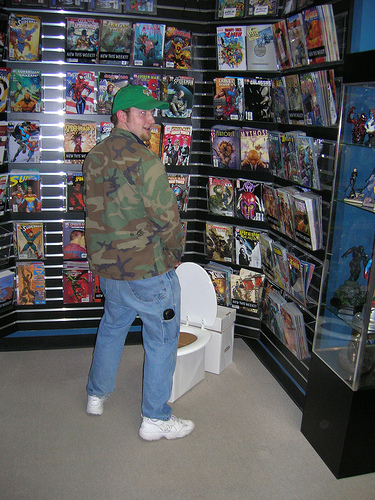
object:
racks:
[0, 0, 349, 382]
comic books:
[273, 4, 340, 71]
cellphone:
[163, 308, 175, 320]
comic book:
[210, 125, 241, 171]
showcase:
[330, 104, 375, 375]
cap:
[111, 83, 170, 116]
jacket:
[82, 128, 185, 282]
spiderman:
[62, 269, 97, 304]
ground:
[0, 334, 375, 500]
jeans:
[85, 267, 181, 421]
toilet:
[168, 261, 219, 405]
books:
[213, 0, 341, 129]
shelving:
[0, 1, 349, 384]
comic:
[7, 120, 42, 164]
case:
[162, 308, 179, 345]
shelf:
[41, 16, 67, 66]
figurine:
[331, 245, 371, 313]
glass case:
[300, 80, 374, 481]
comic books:
[206, 3, 341, 361]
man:
[82, 84, 195, 442]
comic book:
[14, 222, 44, 260]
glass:
[313, 83, 375, 387]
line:
[4, 325, 144, 339]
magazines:
[204, 0, 341, 363]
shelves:
[204, 0, 348, 383]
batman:
[10, 122, 39, 163]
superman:
[19, 124, 40, 163]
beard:
[140, 131, 151, 141]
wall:
[201, 0, 375, 414]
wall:
[0, 8, 212, 352]